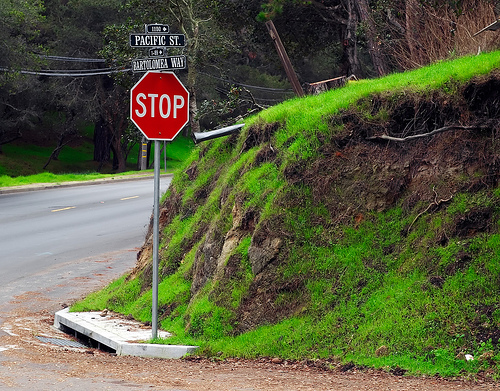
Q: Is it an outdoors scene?
A: Yes, it is outdoors.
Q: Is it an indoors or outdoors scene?
A: It is outdoors.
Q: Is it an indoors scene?
A: No, it is outdoors.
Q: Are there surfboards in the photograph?
A: No, there are no surfboards.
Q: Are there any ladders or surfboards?
A: No, there are no surfboards or ladders.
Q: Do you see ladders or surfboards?
A: No, there are no surfboards or ladders.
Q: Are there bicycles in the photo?
A: No, there are no bicycles.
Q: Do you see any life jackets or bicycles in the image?
A: No, there are no bicycles or life jackets.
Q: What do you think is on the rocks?
A: The moss is on the rocks.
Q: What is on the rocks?
A: The moss is on the rocks.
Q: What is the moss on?
A: The moss is on the rocks.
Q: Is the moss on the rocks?
A: Yes, the moss is on the rocks.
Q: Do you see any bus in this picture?
A: No, there are no buses.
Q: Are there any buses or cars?
A: No, there are no buses or cars.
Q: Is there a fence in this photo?
A: No, there are no fences.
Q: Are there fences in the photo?
A: No, there are no fences.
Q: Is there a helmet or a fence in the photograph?
A: No, there are no fences or helmets.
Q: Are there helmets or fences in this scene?
A: No, there are no fences or helmets.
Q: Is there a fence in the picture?
A: No, there are no fences.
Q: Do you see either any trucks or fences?
A: No, there are no fences or trucks.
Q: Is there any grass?
A: Yes, there is grass.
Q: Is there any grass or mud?
A: Yes, there is grass.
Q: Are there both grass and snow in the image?
A: No, there is grass but no snow.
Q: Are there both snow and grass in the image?
A: No, there is grass but no snow.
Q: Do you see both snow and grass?
A: No, there is grass but no snow.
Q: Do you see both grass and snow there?
A: No, there is grass but no snow.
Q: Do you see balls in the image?
A: No, there are no balls.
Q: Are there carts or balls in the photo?
A: No, there are no balls or carts.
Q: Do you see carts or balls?
A: No, there are no balls or carts.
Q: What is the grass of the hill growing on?
A: The grass is growing on the hill.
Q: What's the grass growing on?
A: The grass is growing on the hill.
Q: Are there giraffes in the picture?
A: No, there are no giraffes.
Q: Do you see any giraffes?
A: No, there are no giraffes.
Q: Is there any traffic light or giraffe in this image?
A: No, there are no giraffes or traffic lights.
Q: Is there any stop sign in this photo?
A: Yes, there is a stop sign.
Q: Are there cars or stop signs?
A: Yes, there is a stop sign.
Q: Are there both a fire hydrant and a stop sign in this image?
A: No, there is a stop sign but no fire hydrants.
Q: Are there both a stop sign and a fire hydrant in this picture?
A: No, there is a stop sign but no fire hydrants.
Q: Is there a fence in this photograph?
A: No, there are no fences.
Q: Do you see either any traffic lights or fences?
A: No, there are no fences or traffic lights.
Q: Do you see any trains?
A: No, there are no trains.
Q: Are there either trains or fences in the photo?
A: No, there are no trains or fences.